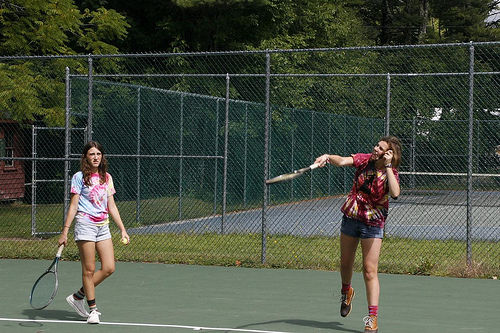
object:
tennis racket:
[264, 162, 326, 185]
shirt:
[67, 169, 116, 227]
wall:
[67, 79, 386, 211]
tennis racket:
[28, 245, 64, 310]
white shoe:
[87, 307, 102, 324]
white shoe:
[62, 292, 91, 320]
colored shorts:
[336, 211, 387, 240]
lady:
[310, 134, 404, 332]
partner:
[57, 139, 133, 326]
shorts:
[73, 214, 114, 241]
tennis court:
[0, 256, 499, 332]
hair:
[378, 135, 401, 173]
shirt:
[338, 151, 400, 228]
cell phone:
[379, 147, 391, 162]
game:
[28, 134, 404, 332]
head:
[83, 141, 103, 169]